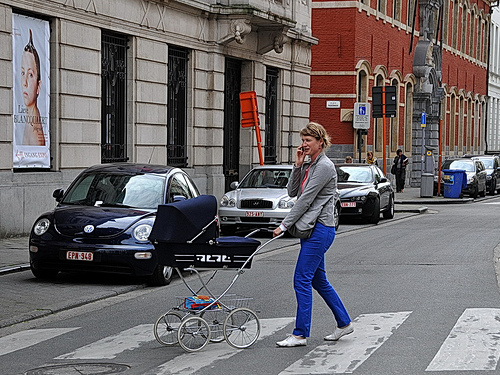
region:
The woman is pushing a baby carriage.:
[140, 96, 381, 366]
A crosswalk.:
[0, 275, 495, 370]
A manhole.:
[25, 345, 129, 374]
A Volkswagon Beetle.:
[20, 146, 210, 276]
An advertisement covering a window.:
[0, 10, 60, 165]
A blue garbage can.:
[435, 165, 465, 201]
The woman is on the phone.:
[275, 115, 350, 245]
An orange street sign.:
[232, 85, 277, 170]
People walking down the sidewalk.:
[337, 140, 408, 195]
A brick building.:
[310, 0, 486, 186]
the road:
[308, 256, 385, 373]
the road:
[293, 198, 417, 365]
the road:
[349, 244, 441, 362]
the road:
[330, 205, 486, 373]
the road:
[295, 225, 367, 354]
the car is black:
[45, 42, 180, 263]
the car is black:
[48, 96, 197, 367]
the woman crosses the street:
[278, 122, 352, 344]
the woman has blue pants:
[291, 223, 343, 335]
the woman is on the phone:
[298, 145, 303, 149]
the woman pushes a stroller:
[152, 195, 279, 349]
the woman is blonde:
[303, 122, 330, 145]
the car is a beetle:
[28, 168, 220, 280]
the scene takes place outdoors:
[0, 0, 499, 372]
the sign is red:
[242, 94, 264, 159]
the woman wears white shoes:
[276, 321, 351, 346]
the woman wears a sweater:
[281, 156, 337, 232]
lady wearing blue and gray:
[270, 119, 357, 351]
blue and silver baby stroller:
[144, 188, 289, 355]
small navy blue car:
[23, 148, 211, 289]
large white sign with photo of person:
[13, 10, 50, 167]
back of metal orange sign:
[238, 90, 260, 131]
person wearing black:
[387, 148, 411, 194]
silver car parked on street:
[216, 159, 340, 238]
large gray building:
[0, 0, 315, 238]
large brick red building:
[311, 1, 489, 187]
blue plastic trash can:
[441, 168, 468, 201]